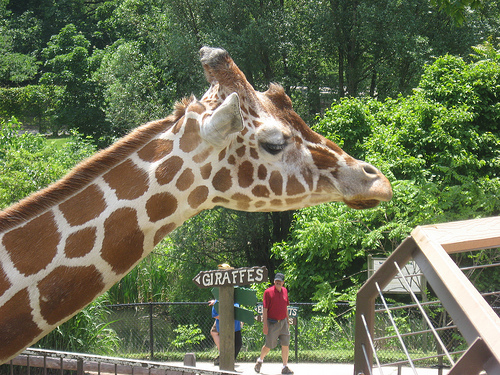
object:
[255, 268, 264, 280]
word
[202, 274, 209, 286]
letter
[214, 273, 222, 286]
letter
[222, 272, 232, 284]
letter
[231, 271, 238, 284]
letter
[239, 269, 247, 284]
letter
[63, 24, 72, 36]
leaves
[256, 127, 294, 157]
eye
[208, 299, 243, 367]
man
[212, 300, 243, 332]
shirt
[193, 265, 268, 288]
sign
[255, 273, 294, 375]
man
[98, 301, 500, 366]
fence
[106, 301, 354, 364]
rail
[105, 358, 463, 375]
path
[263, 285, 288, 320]
shirt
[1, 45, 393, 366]
giraffe